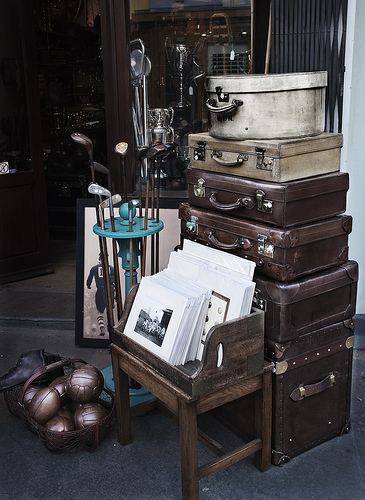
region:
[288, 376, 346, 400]
buckle on old fashioned steam trunk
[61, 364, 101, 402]
brown balls in basket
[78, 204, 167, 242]
blue holder top of golf clubs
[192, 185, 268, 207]
brown handle on suitcase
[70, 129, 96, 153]
head of brown golf club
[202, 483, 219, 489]
white spot on the blue carpet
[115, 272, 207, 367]
white print on bench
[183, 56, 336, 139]
old fashioned white round luggage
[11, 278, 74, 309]
step on the floor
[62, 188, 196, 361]
black and white frame on picture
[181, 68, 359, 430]
large antique stack of luggage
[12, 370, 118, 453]
brown basket of bronze sports balls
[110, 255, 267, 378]
large stack of old pictures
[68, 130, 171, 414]
antique golf clubs and stand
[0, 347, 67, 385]
antique black sports shoes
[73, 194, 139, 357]
antique soccor player photo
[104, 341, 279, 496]
antique brown wooden bench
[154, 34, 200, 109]
trophy in the store window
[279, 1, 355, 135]
black store front lock gate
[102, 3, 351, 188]
antique store window front merchandise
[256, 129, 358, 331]
suit cases stacked on top of each other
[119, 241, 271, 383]
a crate filled with pictures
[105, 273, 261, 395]
the crate is brown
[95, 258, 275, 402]
the crate is made of wood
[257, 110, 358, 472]
a trunk under all the suit cases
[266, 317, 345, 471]
the trunk is brown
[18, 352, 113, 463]
a basket with balls in it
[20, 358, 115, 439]
the balls are copper colored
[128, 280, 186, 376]
the pictures are black and white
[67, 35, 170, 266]
a golf club holder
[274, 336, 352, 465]
Brown leather trunk with handle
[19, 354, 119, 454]
Red basket of brown metal balls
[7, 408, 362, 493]
Blue carpet on floor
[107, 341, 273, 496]
Brown bench holding box of photos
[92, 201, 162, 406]
Turquoise stand holding golf clubs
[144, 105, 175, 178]
Silver trophy on shelf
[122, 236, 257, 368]
Stack of prints with white frames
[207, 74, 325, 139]
Round white hat box with handle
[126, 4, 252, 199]
Trophy case with glass front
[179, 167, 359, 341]
Three stacked brown suit cases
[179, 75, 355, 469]
stack of six suitcases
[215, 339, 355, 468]
dark brown trunk on bottom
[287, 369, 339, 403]
handle of dark brown trunk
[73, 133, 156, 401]
blue golf club holder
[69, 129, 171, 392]
golf clubs in holder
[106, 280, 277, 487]
table photo prints are stacked on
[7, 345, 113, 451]
basket full of golden balls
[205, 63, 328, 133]
light colored suitcase on top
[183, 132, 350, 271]
three suitcases stacked up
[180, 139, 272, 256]
gold buckles on suitcases